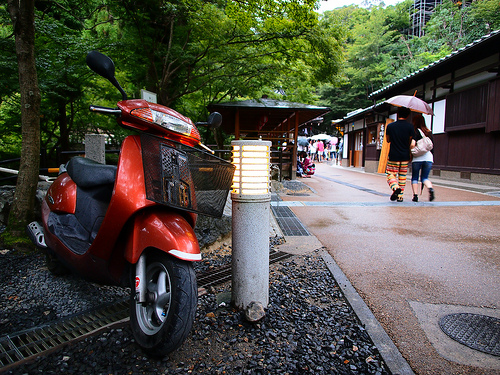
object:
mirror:
[77, 50, 128, 101]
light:
[223, 132, 271, 201]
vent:
[4, 283, 154, 373]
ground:
[0, 161, 499, 375]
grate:
[435, 313, 497, 357]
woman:
[410, 118, 436, 202]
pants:
[383, 155, 410, 199]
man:
[383, 109, 423, 204]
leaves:
[273, 20, 315, 51]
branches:
[216, 18, 303, 79]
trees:
[2, 1, 349, 158]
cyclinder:
[229, 188, 274, 319]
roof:
[213, 95, 326, 112]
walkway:
[274, 155, 498, 365]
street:
[289, 159, 498, 371]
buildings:
[367, 31, 500, 187]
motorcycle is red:
[28, 45, 203, 370]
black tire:
[128, 244, 198, 359]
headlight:
[126, 102, 204, 148]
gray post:
[228, 193, 273, 312]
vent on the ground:
[271, 188, 310, 250]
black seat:
[66, 153, 128, 197]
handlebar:
[82, 103, 131, 116]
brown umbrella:
[382, 90, 437, 117]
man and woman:
[380, 103, 435, 203]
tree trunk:
[6, 1, 47, 230]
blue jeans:
[409, 161, 432, 189]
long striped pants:
[383, 154, 406, 205]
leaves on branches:
[176, 3, 359, 100]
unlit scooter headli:
[121, 99, 208, 153]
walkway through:
[5, 20, 304, 283]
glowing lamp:
[225, 137, 274, 311]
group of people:
[296, 129, 352, 181]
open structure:
[211, 100, 331, 182]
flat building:
[405, 0, 439, 39]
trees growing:
[171, 3, 384, 109]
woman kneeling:
[297, 148, 322, 176]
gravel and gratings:
[268, 255, 403, 374]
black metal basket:
[140, 129, 236, 221]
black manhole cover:
[439, 305, 500, 359]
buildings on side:
[328, 21, 500, 185]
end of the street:
[296, 155, 358, 187]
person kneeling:
[295, 146, 324, 182]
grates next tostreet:
[285, 198, 395, 374]